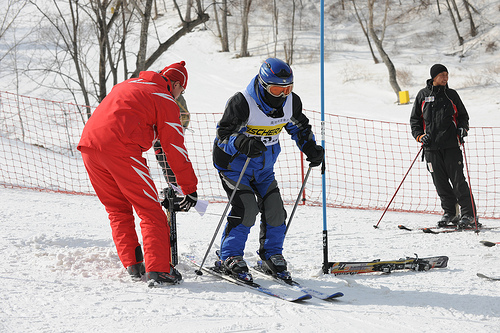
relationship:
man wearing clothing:
[407, 62, 479, 227] [408, 78, 477, 226]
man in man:
[210, 58, 327, 283] [210, 58, 327, 283]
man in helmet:
[219, 61, 333, 296] [253, 66, 291, 105]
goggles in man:
[259, 81, 302, 98] [202, 53, 314, 296]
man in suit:
[74, 62, 194, 283] [104, 72, 159, 257]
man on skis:
[74, 62, 194, 283] [182, 247, 352, 315]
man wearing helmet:
[210, 58, 327, 283] [261, 57, 295, 87]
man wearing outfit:
[74, 62, 194, 283] [75, 70, 199, 268]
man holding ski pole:
[407, 62, 479, 227] [452, 134, 479, 222]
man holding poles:
[407, 62, 479, 227] [373, 142, 428, 228]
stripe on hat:
[165, 68, 184, 80] [161, 64, 188, 83]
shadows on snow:
[183, 275, 496, 317] [1, 0, 499, 331]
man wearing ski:
[407, 62, 479, 227] [419, 220, 499, 233]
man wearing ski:
[407, 62, 479, 227] [395, 222, 485, 231]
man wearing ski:
[210, 58, 327, 283] [185, 254, 315, 309]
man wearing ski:
[210, 58, 327, 283] [244, 257, 344, 305]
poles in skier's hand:
[168, 146, 334, 263] [228, 130, 330, 169]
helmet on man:
[258, 56, 293, 104] [210, 58, 327, 283]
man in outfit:
[74, 62, 194, 283] [75, 70, 199, 288]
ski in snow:
[320, 255, 450, 275] [0, 86, 494, 331]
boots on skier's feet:
[208, 247, 304, 294] [211, 243, 294, 277]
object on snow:
[397, 87, 411, 103] [1, 0, 499, 331]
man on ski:
[210, 58, 327, 283] [253, 248, 345, 301]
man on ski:
[210, 58, 327, 283] [201, 260, 313, 304]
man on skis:
[407, 62, 479, 227] [387, 220, 482, 241]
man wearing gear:
[74, 62, 194, 283] [72, 61, 199, 290]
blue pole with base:
[318, 2, 330, 278] [312, 227, 337, 285]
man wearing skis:
[210, 58, 327, 283] [190, 257, 343, 304]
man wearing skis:
[407, 70, 479, 227] [395, 223, 495, 234]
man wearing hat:
[74, 62, 194, 283] [161, 63, 186, 86]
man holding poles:
[210, 58, 327, 283] [187, 118, 324, 280]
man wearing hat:
[407, 62, 479, 227] [423, 58, 445, 83]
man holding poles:
[74, 62, 194, 283] [365, 123, 483, 233]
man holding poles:
[74, 62, 194, 283] [195, 143, 335, 281]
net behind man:
[326, 116, 406, 219] [74, 62, 194, 283]